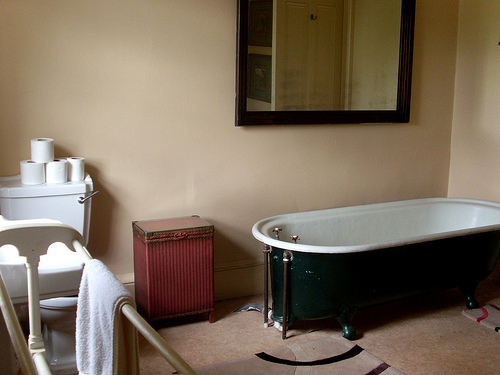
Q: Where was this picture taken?
A: In the bathroom.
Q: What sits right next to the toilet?
A: A red hamper.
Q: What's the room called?
A: Bathroom.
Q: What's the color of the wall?
A: Beige.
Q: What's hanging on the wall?
A: Mirror.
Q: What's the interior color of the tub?
A: White.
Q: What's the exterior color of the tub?
A: Dark green.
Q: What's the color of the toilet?
A: White.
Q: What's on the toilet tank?
A: Toilet paper rolls.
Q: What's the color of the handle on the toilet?
A: Silver.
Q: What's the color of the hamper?
A: Red.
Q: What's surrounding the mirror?
A: Wooden frame.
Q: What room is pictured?
A: Bathroom.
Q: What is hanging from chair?
A: Towel.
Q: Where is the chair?
A: Left.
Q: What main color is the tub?
A: Black.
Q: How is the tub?
A: Standalone.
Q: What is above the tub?
A: Mirror.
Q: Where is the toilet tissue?
A: On toilet.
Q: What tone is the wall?
A: Beige.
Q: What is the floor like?
A: Tiled.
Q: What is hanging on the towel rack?
A: A white towel.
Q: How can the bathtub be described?
A: A vintage green and white claw foot tub.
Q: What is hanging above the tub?
A: A mirror with a wooden frame.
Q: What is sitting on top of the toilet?
A: Four rolls of toilet paper.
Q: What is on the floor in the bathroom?
A: A rug.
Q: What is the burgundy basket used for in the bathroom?
A: A hamper.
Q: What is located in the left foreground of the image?
A: A towel rack.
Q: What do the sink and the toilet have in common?
A: They are white and porcelain.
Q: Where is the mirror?
A: Above the bathtub.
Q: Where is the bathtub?
A: Beneath the mirror.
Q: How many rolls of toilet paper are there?
A: Four.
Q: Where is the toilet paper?
A: On the toilet.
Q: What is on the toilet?
A: Toilet paper rolls.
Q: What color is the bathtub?
A: Black and white.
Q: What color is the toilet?
A: White.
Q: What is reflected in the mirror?
A: A door.